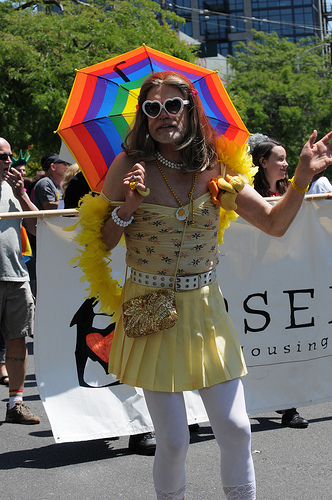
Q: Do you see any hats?
A: Yes, there is a hat.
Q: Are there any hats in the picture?
A: Yes, there is a hat.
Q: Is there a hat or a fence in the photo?
A: Yes, there is a hat.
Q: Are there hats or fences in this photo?
A: Yes, there is a hat.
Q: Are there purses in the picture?
A: Yes, there is a purse.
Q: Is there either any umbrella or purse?
A: Yes, there is a purse.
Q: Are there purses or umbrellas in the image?
A: Yes, there is a purse.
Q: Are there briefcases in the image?
A: No, there are no briefcases.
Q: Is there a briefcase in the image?
A: No, there are no briefcases.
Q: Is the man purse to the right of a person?
A: Yes, the purse is to the right of a person.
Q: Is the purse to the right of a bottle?
A: No, the purse is to the right of a person.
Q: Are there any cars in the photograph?
A: No, there are no cars.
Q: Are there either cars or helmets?
A: No, there are no cars or helmets.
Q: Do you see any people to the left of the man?
A: Yes, there is a person to the left of the man.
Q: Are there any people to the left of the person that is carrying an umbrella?
A: Yes, there is a person to the left of the man.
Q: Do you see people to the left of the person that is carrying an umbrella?
A: Yes, there is a person to the left of the man.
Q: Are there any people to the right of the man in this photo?
A: No, the person is to the left of the man.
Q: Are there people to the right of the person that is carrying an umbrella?
A: No, the person is to the left of the man.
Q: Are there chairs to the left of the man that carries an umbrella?
A: No, there is a person to the left of the man.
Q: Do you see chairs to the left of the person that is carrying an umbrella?
A: No, there is a person to the left of the man.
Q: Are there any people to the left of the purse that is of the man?
A: Yes, there is a person to the left of the purse.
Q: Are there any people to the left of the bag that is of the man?
A: Yes, there is a person to the left of the purse.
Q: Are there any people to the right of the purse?
A: No, the person is to the left of the purse.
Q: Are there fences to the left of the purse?
A: No, there is a person to the left of the purse.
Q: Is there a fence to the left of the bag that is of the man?
A: No, there is a person to the left of the purse.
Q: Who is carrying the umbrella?
A: The man is carrying the umbrella.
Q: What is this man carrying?
A: The man is carrying an umbrella.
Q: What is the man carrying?
A: The man is carrying an umbrella.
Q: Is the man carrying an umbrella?
A: Yes, the man is carrying an umbrella.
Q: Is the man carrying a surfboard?
A: No, the man is carrying an umbrella.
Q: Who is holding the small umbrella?
A: The man is holding the umbrella.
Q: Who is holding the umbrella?
A: The man is holding the umbrella.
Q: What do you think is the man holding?
A: The man is holding the umbrella.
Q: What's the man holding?
A: The man is holding the umbrella.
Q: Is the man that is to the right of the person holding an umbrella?
A: Yes, the man is holding an umbrella.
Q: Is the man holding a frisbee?
A: No, the man is holding an umbrella.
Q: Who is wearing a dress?
A: The man is wearing a dress.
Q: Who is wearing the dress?
A: The man is wearing a dress.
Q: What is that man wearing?
A: The man is wearing a dress.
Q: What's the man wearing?
A: The man is wearing a dress.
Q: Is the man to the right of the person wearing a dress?
A: Yes, the man is wearing a dress.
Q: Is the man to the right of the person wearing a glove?
A: No, the man is wearing a dress.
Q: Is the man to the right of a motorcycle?
A: No, the man is to the right of a person.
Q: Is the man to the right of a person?
A: Yes, the man is to the right of a person.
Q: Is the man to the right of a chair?
A: No, the man is to the right of a person.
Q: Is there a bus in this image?
A: No, there are no buses.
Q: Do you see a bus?
A: No, there are no buses.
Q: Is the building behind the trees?
A: Yes, the building is behind the trees.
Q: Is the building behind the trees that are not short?
A: Yes, the building is behind the trees.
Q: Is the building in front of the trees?
A: No, the building is behind the trees.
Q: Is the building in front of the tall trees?
A: No, the building is behind the trees.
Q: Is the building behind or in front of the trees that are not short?
A: The building is behind the trees.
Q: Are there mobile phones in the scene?
A: No, there are no mobile phones.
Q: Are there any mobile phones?
A: No, there are no mobile phones.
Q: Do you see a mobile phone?
A: No, there are no cell phones.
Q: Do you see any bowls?
A: No, there are no bowls.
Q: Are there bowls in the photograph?
A: No, there are no bowls.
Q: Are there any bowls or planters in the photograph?
A: No, there are no bowls or planters.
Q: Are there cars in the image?
A: No, there are no cars.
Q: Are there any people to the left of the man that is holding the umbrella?
A: Yes, there is a person to the left of the man.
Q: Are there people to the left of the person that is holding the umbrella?
A: Yes, there is a person to the left of the man.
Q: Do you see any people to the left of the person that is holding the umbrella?
A: Yes, there is a person to the left of the man.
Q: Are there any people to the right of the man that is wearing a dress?
A: No, the person is to the left of the man.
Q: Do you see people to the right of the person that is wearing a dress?
A: No, the person is to the left of the man.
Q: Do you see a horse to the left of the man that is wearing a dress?
A: No, there is a person to the left of the man.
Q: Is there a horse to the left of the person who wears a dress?
A: No, there is a person to the left of the man.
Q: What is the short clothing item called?
A: The clothing item is a dress.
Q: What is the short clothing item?
A: The clothing item is a dress.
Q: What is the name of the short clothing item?
A: The clothing item is a dress.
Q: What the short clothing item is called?
A: The clothing item is a dress.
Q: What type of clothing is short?
A: The clothing is a dress.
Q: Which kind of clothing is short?
A: The clothing is a dress.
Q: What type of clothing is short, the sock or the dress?
A: The dress is short.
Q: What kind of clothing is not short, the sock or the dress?
A: The sock is not short.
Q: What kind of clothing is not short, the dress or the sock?
A: The sock is not short.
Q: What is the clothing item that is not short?
A: The clothing item is a sock.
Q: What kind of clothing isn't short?
A: The clothing is a sock.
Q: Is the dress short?
A: Yes, the dress is short.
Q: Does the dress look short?
A: Yes, the dress is short.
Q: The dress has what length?
A: The dress is short.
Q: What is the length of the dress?
A: The dress is short.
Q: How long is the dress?
A: The dress is short.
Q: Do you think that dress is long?
A: No, the dress is short.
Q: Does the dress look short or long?
A: The dress is short.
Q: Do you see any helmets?
A: No, there are no helmets.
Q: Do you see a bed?
A: No, there are no beds.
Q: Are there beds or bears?
A: No, there are no beds or bears.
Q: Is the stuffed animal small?
A: Yes, the stuffed animal is small.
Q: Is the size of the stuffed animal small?
A: Yes, the stuffed animal is small.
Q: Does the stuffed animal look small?
A: Yes, the stuffed animal is small.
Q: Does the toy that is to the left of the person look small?
A: Yes, the stuffed animal is small.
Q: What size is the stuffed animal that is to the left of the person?
A: The stuffed animal is small.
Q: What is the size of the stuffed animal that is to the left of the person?
A: The stuffed animal is small.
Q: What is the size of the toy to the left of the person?
A: The stuffed animal is small.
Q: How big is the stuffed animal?
A: The stuffed animal is small.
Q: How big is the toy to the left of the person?
A: The stuffed animal is small.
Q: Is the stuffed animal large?
A: No, the stuffed animal is small.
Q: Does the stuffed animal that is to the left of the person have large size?
A: No, the stuffed animal is small.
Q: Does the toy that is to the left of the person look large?
A: No, the stuffed animal is small.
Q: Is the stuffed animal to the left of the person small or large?
A: The stuffed animal is small.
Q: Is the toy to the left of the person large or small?
A: The stuffed animal is small.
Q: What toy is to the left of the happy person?
A: The toy is a stuffed animal.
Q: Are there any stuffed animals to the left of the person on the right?
A: Yes, there is a stuffed animal to the left of the person.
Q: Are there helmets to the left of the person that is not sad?
A: No, there is a stuffed animal to the left of the person.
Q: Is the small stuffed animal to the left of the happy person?
A: Yes, the stuffed animal is to the left of the person.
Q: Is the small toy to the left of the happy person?
A: Yes, the stuffed animal is to the left of the person.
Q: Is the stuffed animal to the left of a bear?
A: No, the stuffed animal is to the left of the person.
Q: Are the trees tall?
A: Yes, the trees are tall.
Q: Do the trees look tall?
A: Yes, the trees are tall.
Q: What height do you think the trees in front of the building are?
A: The trees are tall.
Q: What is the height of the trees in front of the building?
A: The trees are tall.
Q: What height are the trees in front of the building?
A: The trees are tall.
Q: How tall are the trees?
A: The trees are tall.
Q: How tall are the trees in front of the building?
A: The trees are tall.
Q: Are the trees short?
A: No, the trees are tall.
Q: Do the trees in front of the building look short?
A: No, the trees are tall.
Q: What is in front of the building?
A: The trees are in front of the building.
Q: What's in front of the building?
A: The trees are in front of the building.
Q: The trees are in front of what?
A: The trees are in front of the building.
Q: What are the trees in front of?
A: The trees are in front of the building.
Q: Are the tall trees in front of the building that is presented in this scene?
A: Yes, the trees are in front of the building.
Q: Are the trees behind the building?
A: No, the trees are in front of the building.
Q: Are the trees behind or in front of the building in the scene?
A: The trees are in front of the building.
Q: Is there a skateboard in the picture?
A: No, there are no skateboards.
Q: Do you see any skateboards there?
A: No, there are no skateboards.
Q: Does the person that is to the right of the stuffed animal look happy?
A: Yes, the person is happy.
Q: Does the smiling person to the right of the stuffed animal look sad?
A: No, the person is happy.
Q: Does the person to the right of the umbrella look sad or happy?
A: The person is happy.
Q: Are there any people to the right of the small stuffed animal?
A: Yes, there is a person to the right of the stuffed animal.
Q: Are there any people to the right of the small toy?
A: Yes, there is a person to the right of the stuffed animal.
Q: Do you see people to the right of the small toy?
A: Yes, there is a person to the right of the stuffed animal.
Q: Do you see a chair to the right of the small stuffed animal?
A: No, there is a person to the right of the stuffed animal.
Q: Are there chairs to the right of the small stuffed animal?
A: No, there is a person to the right of the stuffed animal.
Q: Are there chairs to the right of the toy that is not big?
A: No, there is a person to the right of the stuffed animal.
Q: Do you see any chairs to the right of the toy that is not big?
A: No, there is a person to the right of the stuffed animal.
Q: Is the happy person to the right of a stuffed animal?
A: Yes, the person is to the right of a stuffed animal.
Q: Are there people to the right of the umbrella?
A: Yes, there is a person to the right of the umbrella.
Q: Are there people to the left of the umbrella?
A: No, the person is to the right of the umbrella.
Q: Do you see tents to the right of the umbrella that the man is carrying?
A: No, there is a person to the right of the umbrella.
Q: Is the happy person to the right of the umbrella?
A: Yes, the person is to the right of the umbrella.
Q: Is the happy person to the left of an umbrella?
A: No, the person is to the right of an umbrella.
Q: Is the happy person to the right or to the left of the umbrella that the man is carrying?
A: The person is to the right of the umbrella.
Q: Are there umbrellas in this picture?
A: Yes, there is an umbrella.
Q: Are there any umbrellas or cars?
A: Yes, there is an umbrella.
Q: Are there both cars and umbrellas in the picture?
A: No, there is an umbrella but no cars.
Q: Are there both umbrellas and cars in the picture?
A: No, there is an umbrella but no cars.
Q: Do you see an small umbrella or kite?
A: Yes, there is a small umbrella.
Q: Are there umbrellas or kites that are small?
A: Yes, the umbrella is small.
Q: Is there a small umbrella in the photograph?
A: Yes, there is a small umbrella.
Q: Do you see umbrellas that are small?
A: Yes, there is an umbrella that is small.